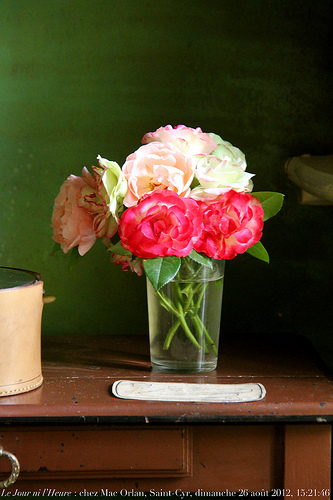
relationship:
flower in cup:
[200, 189, 262, 261] [145, 253, 224, 371]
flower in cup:
[121, 189, 204, 258] [145, 253, 224, 371]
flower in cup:
[50, 174, 112, 255] [145, 253, 224, 371]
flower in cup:
[127, 145, 194, 208] [145, 253, 224, 371]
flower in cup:
[198, 133, 256, 194] [145, 253, 224, 371]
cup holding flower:
[145, 253, 224, 371] [198, 133, 256, 194]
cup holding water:
[145, 253, 224, 371] [154, 279, 217, 366]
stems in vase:
[151, 285, 217, 355] [145, 253, 224, 371]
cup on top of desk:
[145, 253, 224, 371] [2, 329, 331, 497]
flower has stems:
[121, 189, 204, 258] [151, 285, 217, 355]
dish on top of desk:
[112, 379, 264, 403] [2, 329, 331, 497]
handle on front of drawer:
[0, 450, 21, 489] [2, 424, 200, 483]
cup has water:
[145, 253, 224, 371] [154, 279, 217, 366]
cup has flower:
[145, 253, 224, 371] [121, 189, 204, 258]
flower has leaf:
[121, 189, 204, 258] [144, 256, 184, 290]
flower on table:
[121, 189, 204, 258] [2, 329, 331, 497]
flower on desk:
[50, 174, 112, 255] [2, 329, 331, 497]